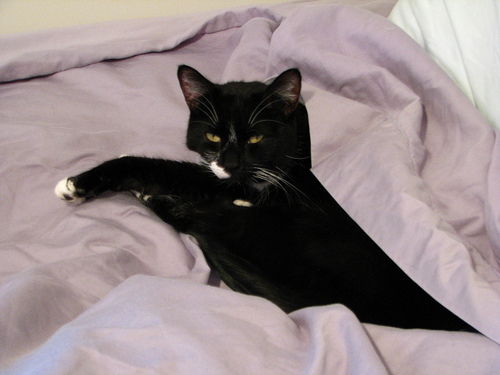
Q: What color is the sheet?
A: Purple.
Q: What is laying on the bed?
A: A cat.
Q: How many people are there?
A: None.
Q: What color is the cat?
A: Black and White.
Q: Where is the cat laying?
A: On the Bed.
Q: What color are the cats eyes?
A: Yellow.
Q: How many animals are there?
A: One.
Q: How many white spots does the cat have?
A: Three.